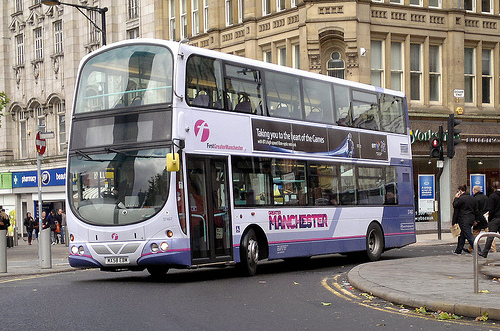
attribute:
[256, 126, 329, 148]
words — white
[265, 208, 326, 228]
words — white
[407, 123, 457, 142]
words — white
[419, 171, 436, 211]
words — white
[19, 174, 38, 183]
words — white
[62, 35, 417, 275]
bus — purple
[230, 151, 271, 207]
window — glassy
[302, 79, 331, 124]
window — glassy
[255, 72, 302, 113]
window — glassy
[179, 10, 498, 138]
building — large, brown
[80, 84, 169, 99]
object — green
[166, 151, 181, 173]
mirror cover — yellow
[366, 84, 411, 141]
window — glassy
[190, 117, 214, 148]
logo — pink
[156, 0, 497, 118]
building — tan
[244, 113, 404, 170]
sign — black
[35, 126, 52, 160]
sign — red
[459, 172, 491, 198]
sign — blue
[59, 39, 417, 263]
double-decker bus — large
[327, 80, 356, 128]
window — glassy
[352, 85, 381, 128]
window — glassy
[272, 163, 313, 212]
window — glassy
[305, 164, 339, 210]
window — glassy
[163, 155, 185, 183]
mirror — yellow 